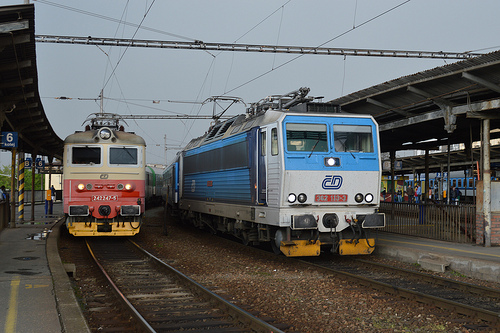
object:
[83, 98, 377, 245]
trains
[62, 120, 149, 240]
train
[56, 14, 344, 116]
wires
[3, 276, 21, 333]
barrier lines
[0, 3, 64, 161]
roof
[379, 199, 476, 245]
railing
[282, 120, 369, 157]
windshield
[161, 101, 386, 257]
train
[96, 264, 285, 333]
track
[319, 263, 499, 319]
track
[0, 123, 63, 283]
platform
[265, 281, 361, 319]
gravel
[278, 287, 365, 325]
rock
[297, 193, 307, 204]
headlights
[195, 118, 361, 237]
train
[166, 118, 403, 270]
train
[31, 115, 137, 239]
train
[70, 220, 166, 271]
train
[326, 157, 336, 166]
lights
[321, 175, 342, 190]
lettering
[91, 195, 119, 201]
numbers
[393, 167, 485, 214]
train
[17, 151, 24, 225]
pole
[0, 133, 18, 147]
sign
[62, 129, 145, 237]
train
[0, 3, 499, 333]
station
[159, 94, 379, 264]
train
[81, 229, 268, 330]
train tracks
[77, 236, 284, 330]
train tracks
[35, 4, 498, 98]
wires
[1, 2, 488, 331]
train station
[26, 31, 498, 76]
train station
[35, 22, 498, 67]
wires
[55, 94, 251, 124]
wires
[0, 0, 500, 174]
sky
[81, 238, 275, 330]
train track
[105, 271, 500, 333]
dirt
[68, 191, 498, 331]
train tracks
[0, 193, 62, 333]
sidewalk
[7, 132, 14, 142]
6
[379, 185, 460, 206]
pedestrians